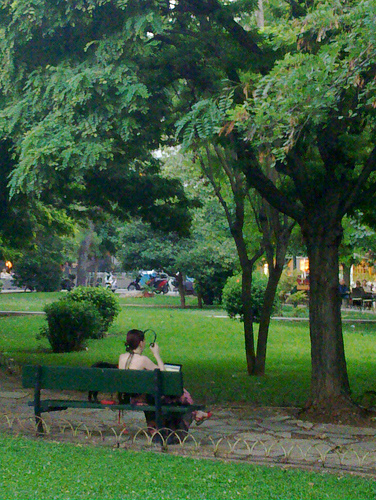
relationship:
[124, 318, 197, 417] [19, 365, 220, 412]
woman sitting on bench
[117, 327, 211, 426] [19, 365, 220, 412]
woman sitting on bench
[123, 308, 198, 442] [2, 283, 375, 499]
woman sitting in park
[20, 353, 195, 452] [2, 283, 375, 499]
bench in park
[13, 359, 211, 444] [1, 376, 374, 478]
bench on sidewalk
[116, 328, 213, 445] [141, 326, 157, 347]
woman putting on head phones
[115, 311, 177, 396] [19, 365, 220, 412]
woman sitting on bench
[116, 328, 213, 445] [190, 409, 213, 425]
woman wearing sandals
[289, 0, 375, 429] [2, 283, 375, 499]
tree in park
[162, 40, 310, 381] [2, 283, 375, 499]
tree in park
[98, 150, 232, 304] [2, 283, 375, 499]
tree in park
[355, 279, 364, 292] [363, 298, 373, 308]
person in chair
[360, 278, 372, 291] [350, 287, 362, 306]
person in chair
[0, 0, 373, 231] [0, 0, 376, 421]
leaves on brown tree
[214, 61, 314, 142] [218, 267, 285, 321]
leaves on bush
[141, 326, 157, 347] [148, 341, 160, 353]
head phones on hand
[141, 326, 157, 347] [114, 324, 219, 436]
head phones on woman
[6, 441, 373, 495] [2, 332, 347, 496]
grass in foreground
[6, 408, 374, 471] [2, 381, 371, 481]
fence along walkway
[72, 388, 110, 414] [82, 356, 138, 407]
legs on animal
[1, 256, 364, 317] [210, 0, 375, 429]
street scene behind tree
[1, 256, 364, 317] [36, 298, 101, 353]
street scene behind bush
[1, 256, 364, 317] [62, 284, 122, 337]
street scene behind bushes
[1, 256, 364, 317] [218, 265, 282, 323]
street scene behind bush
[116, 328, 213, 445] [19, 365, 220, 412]
woman sitting on bench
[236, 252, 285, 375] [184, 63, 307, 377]
forks on tree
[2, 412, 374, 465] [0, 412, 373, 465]
edging like arches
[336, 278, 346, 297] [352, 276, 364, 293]
person facing person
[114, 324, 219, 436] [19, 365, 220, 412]
woman sitting on bench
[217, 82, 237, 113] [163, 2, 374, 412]
leaves on tree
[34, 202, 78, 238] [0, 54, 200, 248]
leaves on tree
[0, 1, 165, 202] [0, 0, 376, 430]
leaves on brown tree